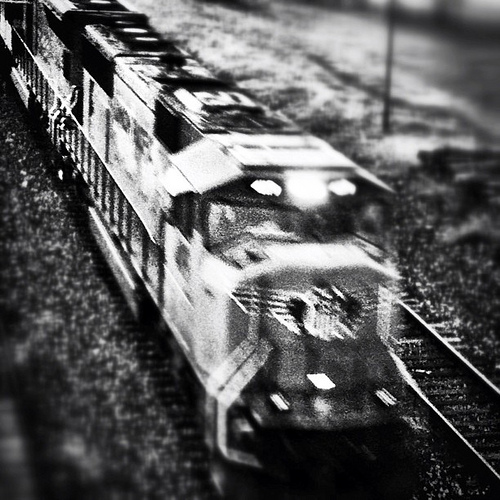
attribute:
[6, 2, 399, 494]
train — running, moving, blurry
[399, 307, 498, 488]
tracks — black, empty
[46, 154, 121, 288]
rail — black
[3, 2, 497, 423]
photo — black, white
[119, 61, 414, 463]
one train — blurry